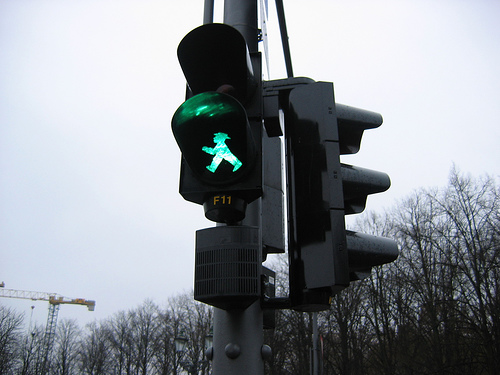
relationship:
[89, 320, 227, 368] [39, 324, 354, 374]
tree by road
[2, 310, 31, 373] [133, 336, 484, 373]
tree by road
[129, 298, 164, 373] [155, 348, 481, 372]
tree on side of road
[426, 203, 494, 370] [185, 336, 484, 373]
tree on side of road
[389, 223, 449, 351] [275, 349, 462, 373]
tree on side of road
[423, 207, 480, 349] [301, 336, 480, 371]
tree on side of road